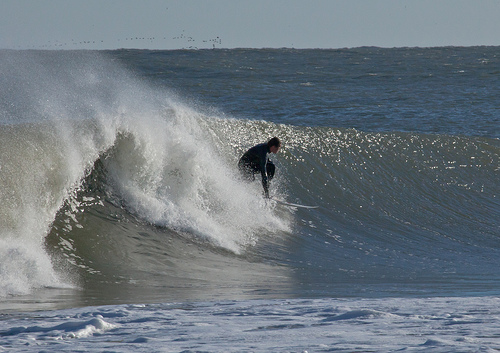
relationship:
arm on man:
[259, 156, 271, 200] [237, 132, 284, 203]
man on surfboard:
[237, 136, 280, 199] [269, 191, 321, 216]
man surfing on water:
[236, 135, 283, 205] [0, 44, 499, 351]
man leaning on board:
[237, 136, 280, 199] [262, 194, 319, 210]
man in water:
[237, 136, 280, 199] [358, 140, 418, 200]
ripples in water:
[338, 198, 447, 240] [33, 143, 492, 295]